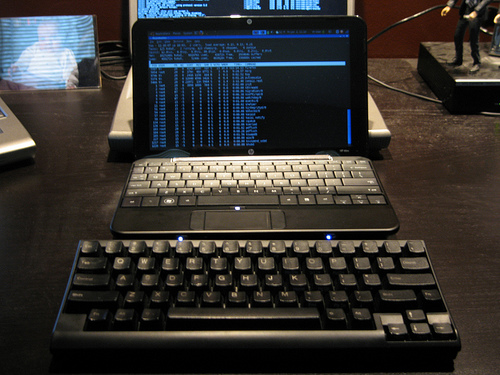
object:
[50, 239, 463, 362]
keyboard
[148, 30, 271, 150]
writing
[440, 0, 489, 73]
figure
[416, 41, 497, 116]
pedestal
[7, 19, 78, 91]
baby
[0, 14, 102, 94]
photo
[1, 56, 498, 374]
table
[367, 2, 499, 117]
cord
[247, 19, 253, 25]
camera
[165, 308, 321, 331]
spacebar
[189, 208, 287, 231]
mouse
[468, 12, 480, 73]
leg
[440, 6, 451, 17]
hand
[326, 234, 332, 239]
light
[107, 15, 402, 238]
laptop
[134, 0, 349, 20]
screen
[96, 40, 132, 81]
cables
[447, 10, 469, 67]
legs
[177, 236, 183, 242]
lights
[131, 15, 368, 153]
display